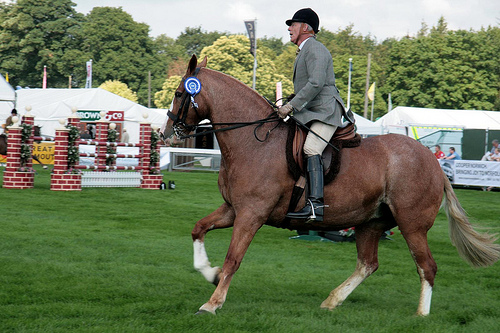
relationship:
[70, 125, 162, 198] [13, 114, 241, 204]
jump on course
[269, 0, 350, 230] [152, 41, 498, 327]
man riding on dressage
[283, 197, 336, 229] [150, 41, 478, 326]
left stirrup on horse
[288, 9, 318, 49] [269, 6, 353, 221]
hat on man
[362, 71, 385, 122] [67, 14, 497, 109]
flag in distance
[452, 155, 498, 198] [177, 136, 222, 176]
sign by fence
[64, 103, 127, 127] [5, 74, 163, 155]
sign on tent